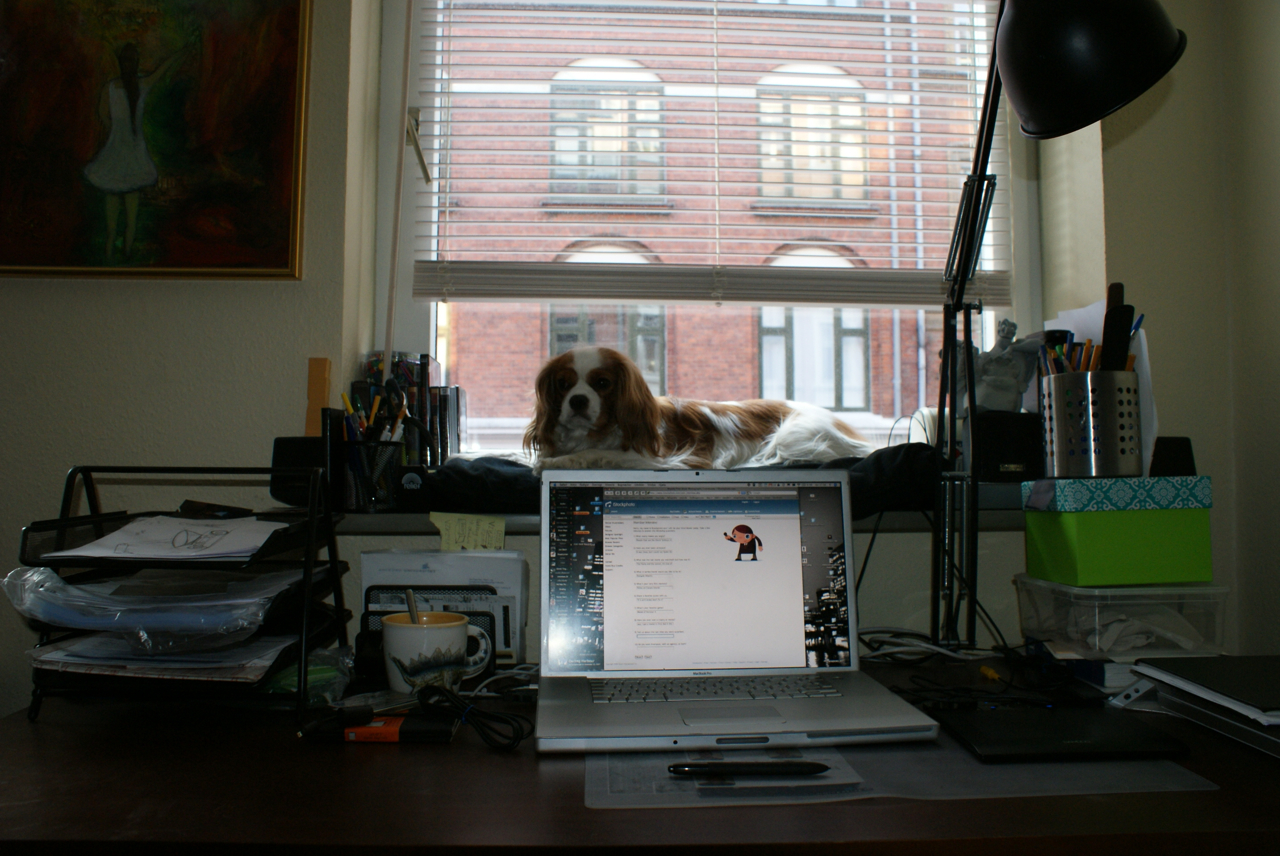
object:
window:
[427, 0, 1014, 460]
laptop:
[534, 468, 942, 752]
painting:
[6, 0, 305, 283]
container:
[1042, 281, 1144, 479]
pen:
[668, 761, 831, 775]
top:
[1022, 475, 1213, 511]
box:
[1022, 475, 1215, 586]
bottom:
[1026, 510, 1213, 588]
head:
[534, 348, 660, 431]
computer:
[538, 469, 938, 751]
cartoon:
[725, 524, 764, 561]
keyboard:
[536, 672, 934, 750]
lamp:
[928, 0, 1188, 649]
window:
[547, 55, 663, 193]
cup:
[382, 610, 490, 693]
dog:
[524, 346, 871, 470]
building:
[421, 0, 1006, 453]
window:
[756, 65, 864, 209]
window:
[545, 238, 661, 396]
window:
[756, 240, 866, 413]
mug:
[382, 610, 492, 693]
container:
[1042, 371, 1140, 476]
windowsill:
[337, 449, 1075, 514]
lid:
[1022, 475, 1211, 511]